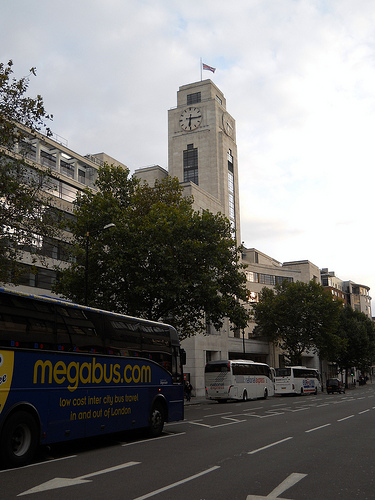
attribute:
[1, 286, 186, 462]
bus — blue, waiting, white, yellow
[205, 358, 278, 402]
bus — white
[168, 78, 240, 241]
tower — tall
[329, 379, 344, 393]
car — black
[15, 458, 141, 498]
arrow — white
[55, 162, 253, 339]
tree — green, tall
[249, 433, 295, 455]
line — white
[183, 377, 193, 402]
person — walking